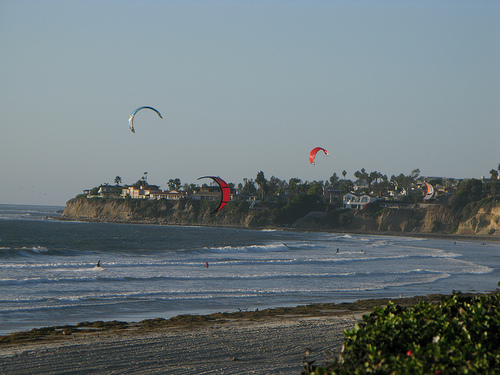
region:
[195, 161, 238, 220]
sail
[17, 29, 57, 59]
white clouds in blue sky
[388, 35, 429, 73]
white clouds in blue sky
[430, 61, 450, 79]
white clouds in blue sky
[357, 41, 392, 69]
white clouds in blue sky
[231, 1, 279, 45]
white clouds in blue sky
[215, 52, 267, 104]
white clouds in blue sky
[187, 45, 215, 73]
white clouds in blue sky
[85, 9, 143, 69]
white clouds in blue sky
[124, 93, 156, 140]
sails in air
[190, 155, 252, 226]
sails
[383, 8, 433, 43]
white clouds in blue sky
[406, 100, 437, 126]
white clouds in blue sky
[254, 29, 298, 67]
white clouds in blue sky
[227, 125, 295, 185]
white clouds in blue sky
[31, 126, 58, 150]
white clouds in blue sky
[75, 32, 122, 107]
white clouds in blue sky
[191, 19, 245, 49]
white clouds in blue sky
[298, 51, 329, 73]
white clouds in blue sky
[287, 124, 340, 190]
sail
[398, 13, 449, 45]
white clouds in blue sky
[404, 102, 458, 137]
white clouds in blue sky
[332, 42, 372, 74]
white clouds in blue sky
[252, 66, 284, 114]
white clouds in blue sky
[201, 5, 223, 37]
white clouds in blue sky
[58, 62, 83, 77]
white clouds in blue sky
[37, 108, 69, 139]
white clouds in blue sky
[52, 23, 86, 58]
white clouds in blue sky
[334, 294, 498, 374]
bush with green leaves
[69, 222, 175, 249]
small ripples on surface of water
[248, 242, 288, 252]
white sea foam on wave surface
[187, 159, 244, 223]
red and black kite in sky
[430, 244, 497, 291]
waves crashing on beach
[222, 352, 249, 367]
rock laying on beach sand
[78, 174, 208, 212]
houses on seaside hill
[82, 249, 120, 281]
person standing in water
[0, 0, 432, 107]
clear sky above ocean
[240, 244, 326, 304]
waves on surface of water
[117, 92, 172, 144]
blue and white sail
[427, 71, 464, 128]
white clouds in blue sky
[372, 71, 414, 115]
white clouds in blue sky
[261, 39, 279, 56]
white clouds in blue sky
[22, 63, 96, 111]
white clouds in blue sky